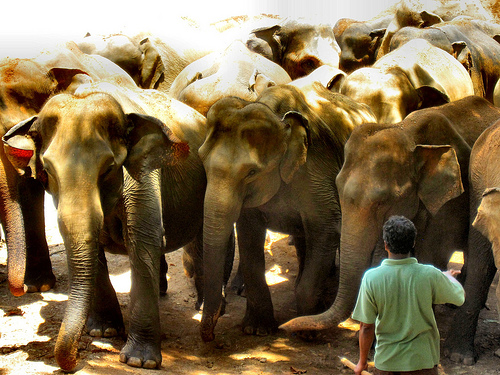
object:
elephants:
[276, 96, 500, 365]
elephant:
[0, 83, 207, 372]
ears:
[112, 113, 194, 186]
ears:
[0, 114, 43, 181]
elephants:
[197, 80, 377, 343]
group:
[0, 1, 499, 372]